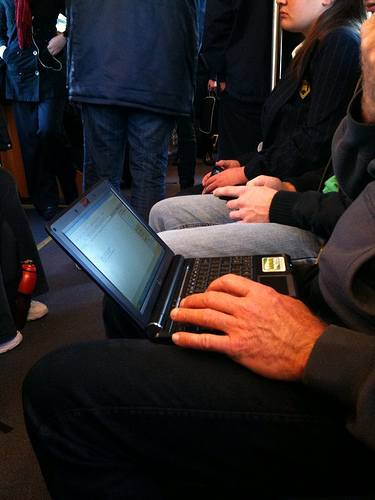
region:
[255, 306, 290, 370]
part of a hanmd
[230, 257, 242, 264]
black key on laptop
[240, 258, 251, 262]
black key on laptop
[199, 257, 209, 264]
black key on laptop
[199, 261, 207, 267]
black key on laptop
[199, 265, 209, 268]
black key on laptop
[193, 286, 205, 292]
black key on laptop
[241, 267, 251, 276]
black key on laptop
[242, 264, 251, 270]
black key on laptop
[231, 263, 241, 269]
black key on laptop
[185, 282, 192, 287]
black key on laptop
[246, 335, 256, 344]
part of an arm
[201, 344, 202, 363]
part of a finger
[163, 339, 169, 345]
edge of a laptop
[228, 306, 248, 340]
part of an arm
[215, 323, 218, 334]
edge of a finger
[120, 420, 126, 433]
side of a leg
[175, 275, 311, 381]
a persons hand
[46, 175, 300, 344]
person using black laptop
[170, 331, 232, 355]
pinky on hand of man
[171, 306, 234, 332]
ring finger on hand of man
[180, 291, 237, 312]
middle finger on hand of man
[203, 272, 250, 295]
poiner finger on hand of man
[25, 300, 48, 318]
tip of white sneaker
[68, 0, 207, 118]
person wearing black jacket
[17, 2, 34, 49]
person wearing red scarf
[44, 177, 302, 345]
open laptop is on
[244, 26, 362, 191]
person wearing dark jacket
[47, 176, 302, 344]
person is using netbook